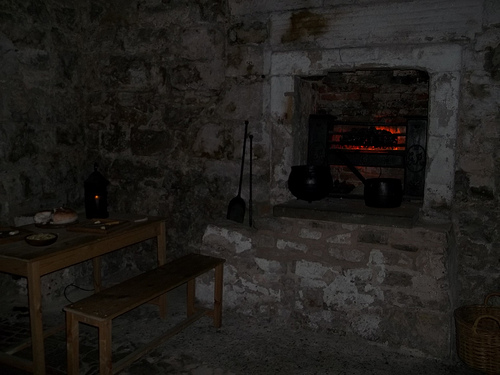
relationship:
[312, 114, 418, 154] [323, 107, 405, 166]
fire place cooking fireplace food cooking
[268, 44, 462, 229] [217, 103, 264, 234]
fireplace has black untensil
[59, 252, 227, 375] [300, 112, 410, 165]
bench by fire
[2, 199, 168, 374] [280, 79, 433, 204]
wooden table by fire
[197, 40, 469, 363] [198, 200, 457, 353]
fireplace has hearth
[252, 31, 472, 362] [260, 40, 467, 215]
stone firebplace has mantle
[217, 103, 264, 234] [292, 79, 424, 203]
fire untensil used for fire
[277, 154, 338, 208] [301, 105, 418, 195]
cast iron pot standing by fire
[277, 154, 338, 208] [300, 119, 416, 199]
iron pot standing by fire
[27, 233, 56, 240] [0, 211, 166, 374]
food on long table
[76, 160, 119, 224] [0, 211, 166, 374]
black latern on long table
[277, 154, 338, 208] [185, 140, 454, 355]
black cauldron on mantle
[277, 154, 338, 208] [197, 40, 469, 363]
block pot on fireplace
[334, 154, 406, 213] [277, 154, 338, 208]
pot on block pot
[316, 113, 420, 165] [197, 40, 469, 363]
fire in fireplace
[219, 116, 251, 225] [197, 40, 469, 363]
scooper for fireplace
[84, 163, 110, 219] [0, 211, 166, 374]
lantern on long table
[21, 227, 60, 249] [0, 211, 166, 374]
food on long table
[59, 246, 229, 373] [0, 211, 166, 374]
bench at long table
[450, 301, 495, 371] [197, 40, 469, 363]
basket by fireplace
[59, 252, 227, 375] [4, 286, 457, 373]
bench on floor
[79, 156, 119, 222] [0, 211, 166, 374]
lantern on long table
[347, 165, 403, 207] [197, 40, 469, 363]
pot on fireplace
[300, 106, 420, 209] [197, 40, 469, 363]
stove in fireplace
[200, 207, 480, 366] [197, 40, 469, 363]
wall in front of fireplace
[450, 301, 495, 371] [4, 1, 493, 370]
basket in room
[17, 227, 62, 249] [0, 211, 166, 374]
bowl on long table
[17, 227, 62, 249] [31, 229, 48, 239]
bowl has food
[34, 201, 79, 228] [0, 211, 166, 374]
bread plate on long table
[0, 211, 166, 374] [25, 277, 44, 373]
long table has leg